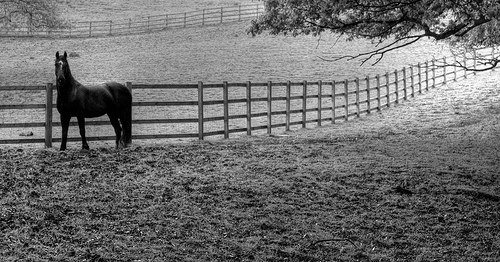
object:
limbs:
[415, 55, 498, 75]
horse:
[35, 39, 148, 155]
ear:
[52, 49, 61, 60]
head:
[42, 43, 82, 90]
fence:
[1, 0, 282, 42]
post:
[41, 80, 57, 151]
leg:
[55, 106, 74, 155]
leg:
[107, 106, 124, 148]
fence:
[0, 40, 499, 152]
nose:
[55, 73, 67, 86]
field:
[2, 9, 499, 85]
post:
[192, 75, 208, 142]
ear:
[62, 49, 69, 59]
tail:
[117, 87, 137, 148]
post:
[217, 74, 235, 143]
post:
[242, 75, 258, 143]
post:
[263, 74, 277, 136]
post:
[281, 72, 297, 136]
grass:
[0, 58, 500, 261]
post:
[298, 74, 310, 129]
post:
[315, 75, 326, 130]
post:
[328, 74, 339, 129]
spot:
[55, 57, 69, 73]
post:
[343, 75, 351, 123]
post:
[353, 70, 363, 123]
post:
[364, 71, 374, 116]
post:
[384, 69, 394, 109]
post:
[374, 70, 385, 112]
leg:
[75, 109, 89, 152]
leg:
[119, 115, 135, 150]